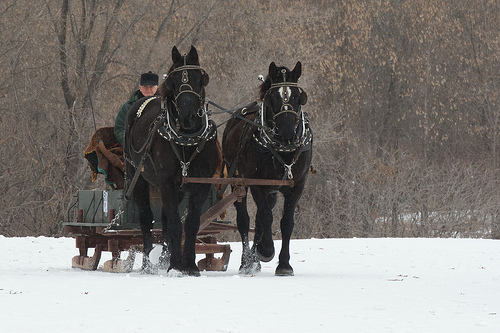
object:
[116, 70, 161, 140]
man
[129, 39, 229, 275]
horse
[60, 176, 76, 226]
trunks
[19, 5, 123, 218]
tree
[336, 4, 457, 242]
tree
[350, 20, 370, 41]
leaves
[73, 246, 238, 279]
vehicle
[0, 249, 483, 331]
snow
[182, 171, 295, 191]
bars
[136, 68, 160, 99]
head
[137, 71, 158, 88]
cap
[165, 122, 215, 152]
neck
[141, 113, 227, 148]
reins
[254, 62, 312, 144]
head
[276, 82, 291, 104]
spot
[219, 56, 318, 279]
horses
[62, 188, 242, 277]
sled